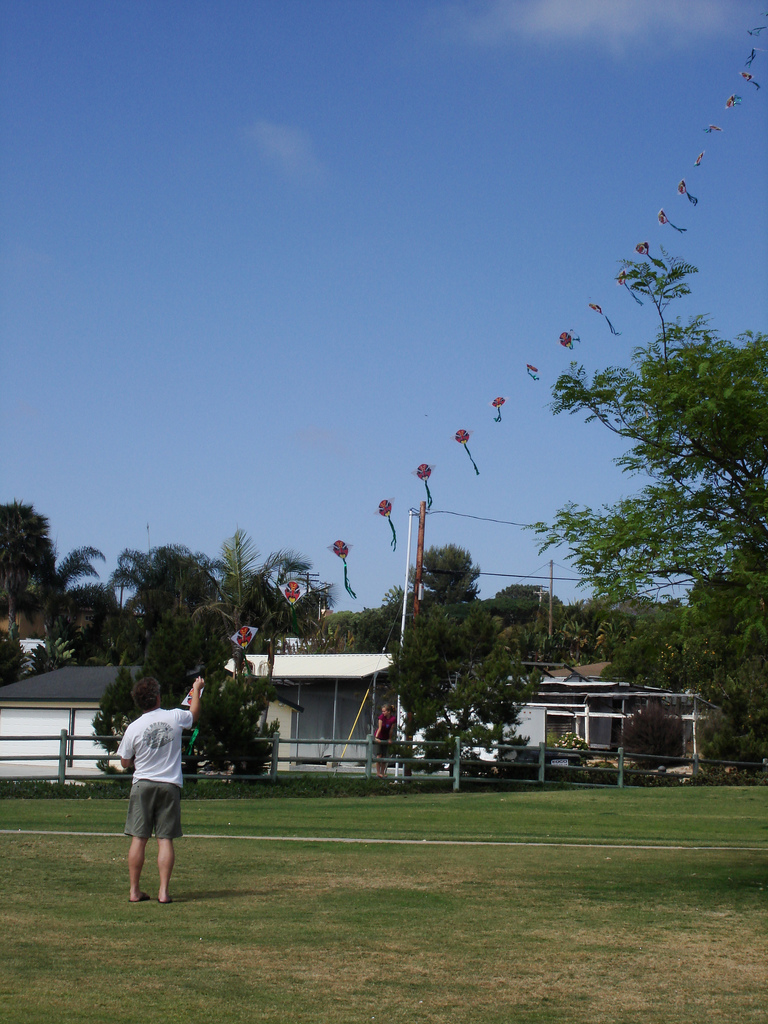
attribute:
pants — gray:
[123, 772, 182, 842]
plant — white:
[550, 727, 585, 755]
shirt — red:
[373, 714, 394, 731]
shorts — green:
[373, 738, 387, 755]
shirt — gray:
[106, 701, 210, 788]